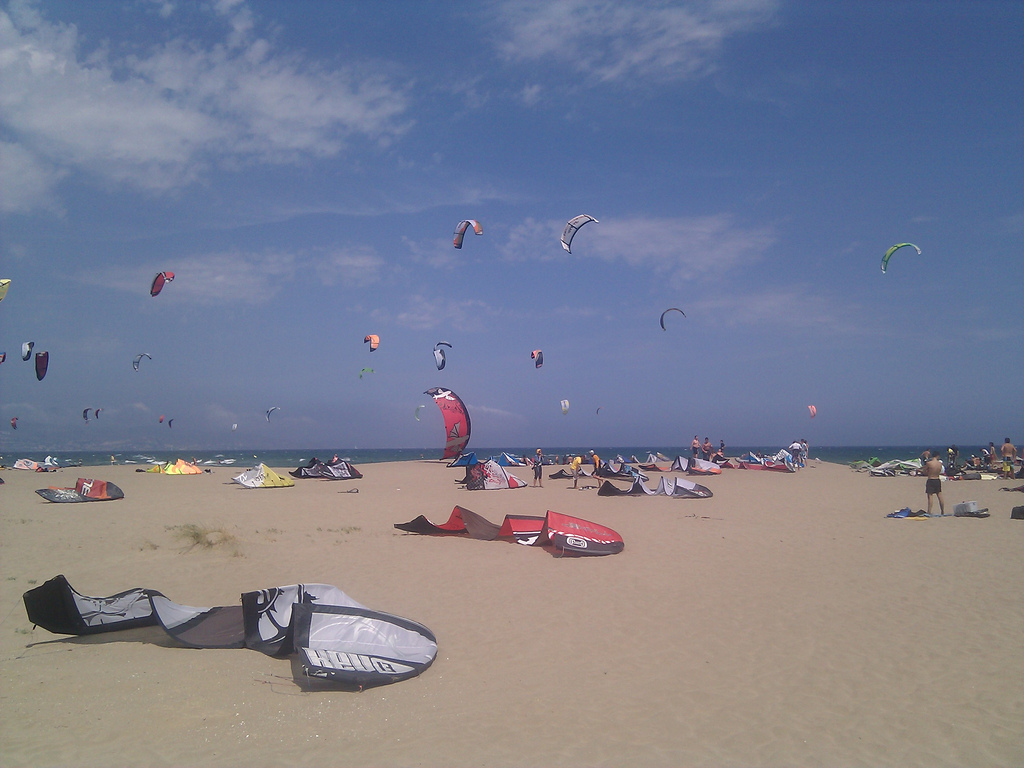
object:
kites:
[27, 479, 712, 689]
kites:
[0, 214, 923, 460]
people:
[917, 453, 949, 518]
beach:
[0, 458, 1024, 768]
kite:
[20, 572, 439, 685]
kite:
[394, 505, 626, 556]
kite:
[424, 386, 473, 462]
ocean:
[0, 445, 1021, 467]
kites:
[0, 450, 792, 689]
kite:
[22, 341, 35, 360]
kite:
[35, 352, 48, 382]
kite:
[150, 272, 175, 297]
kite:
[454, 220, 484, 250]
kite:
[559, 214, 597, 254]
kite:
[881, 243, 920, 274]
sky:
[0, 0, 1022, 444]